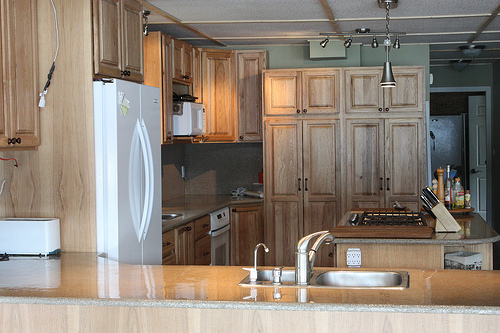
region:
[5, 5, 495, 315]
a scene inside here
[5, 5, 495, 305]
a kitchen at a house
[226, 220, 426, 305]
a silver sink here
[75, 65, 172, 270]
a white icebox here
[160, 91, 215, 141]
a white microwave here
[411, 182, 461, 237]
a knife set here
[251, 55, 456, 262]
some tan cupboards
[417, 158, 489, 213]
some kitchen items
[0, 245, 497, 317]
gray marble counter top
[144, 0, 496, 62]
a white ceiling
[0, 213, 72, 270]
a toaster sitting on a counter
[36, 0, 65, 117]
an electrical cord hanging from the ceiling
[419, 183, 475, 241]
a rack of kitchen knives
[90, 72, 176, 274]
a closed white refrigerator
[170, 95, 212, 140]
a microwave recessed into the cabinets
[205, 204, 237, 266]
the front of a closed dishwasher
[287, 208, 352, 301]
a silver kitchen faucet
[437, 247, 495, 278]
the top of a trash can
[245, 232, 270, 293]
a drinking water dispenser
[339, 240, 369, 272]
a row of electrical outlets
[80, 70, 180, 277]
A refrigerator is in the kitchen.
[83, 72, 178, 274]
The refrigerator is white.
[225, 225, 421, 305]
A sink is in the foreground.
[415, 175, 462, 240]
A knife block is on the counter.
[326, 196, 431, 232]
A cooking grill is in the counter.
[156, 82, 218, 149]
A microwave is near the cabinets.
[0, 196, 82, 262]
A toaster is on the counter.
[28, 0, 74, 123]
A cord hangs from the ceiling.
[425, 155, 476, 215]
Bottles and a pepper mill are on the counter.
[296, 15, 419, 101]
Lights are attached to the ceiling.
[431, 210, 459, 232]
a wooden knife holder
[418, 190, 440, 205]
black plastic handles on the knives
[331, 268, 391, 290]
a stainless steel sink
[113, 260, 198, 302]
a reflection on the shiny counter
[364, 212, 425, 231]
black metal burner brackets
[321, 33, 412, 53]
silver track lights on the ceiling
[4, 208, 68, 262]
a white toaster against the wall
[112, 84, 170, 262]
a white refridgerator with handles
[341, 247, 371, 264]
a white electrical socket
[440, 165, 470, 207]
condiments on a wooden tray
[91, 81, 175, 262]
This is a white fridge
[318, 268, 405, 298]
This is a sink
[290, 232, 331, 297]
This is a tap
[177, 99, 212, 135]
This is a microwave oven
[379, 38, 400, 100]
this is a kitchen light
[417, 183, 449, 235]
Theses are knives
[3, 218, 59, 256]
This is a toasting machine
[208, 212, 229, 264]
This is a cooker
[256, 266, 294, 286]
This is a sink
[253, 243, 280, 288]
These are taps